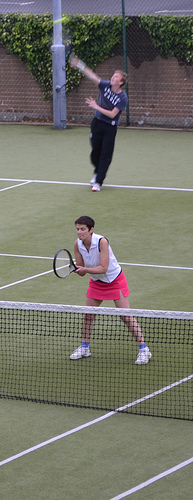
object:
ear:
[89, 227, 94, 235]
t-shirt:
[94, 78, 128, 126]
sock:
[139, 344, 146, 350]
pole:
[50, 0, 66, 129]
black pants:
[89, 116, 117, 186]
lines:
[0, 176, 193, 465]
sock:
[81, 342, 90, 348]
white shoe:
[90, 173, 101, 191]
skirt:
[86, 268, 130, 301]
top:
[77, 232, 121, 283]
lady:
[70, 215, 153, 366]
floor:
[67, 43, 83, 53]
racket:
[53, 248, 79, 279]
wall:
[1, 0, 193, 128]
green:
[1, 121, 193, 500]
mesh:
[0, 299, 193, 421]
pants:
[89, 116, 117, 186]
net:
[0, 298, 191, 422]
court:
[0, 123, 193, 499]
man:
[84, 70, 127, 192]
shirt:
[78, 232, 122, 283]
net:
[0, 310, 193, 420]